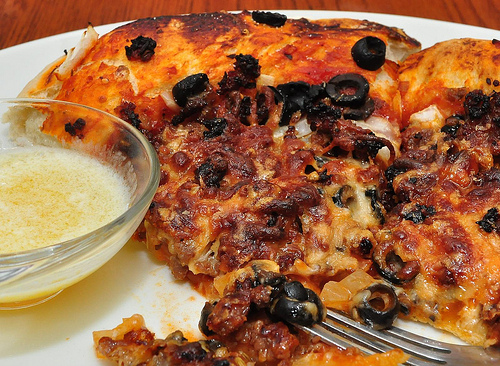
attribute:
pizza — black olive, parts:
[44, 13, 441, 362]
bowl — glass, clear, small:
[0, 111, 167, 265]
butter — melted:
[4, 144, 90, 221]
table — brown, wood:
[6, 16, 498, 328]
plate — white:
[22, 23, 479, 360]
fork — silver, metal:
[309, 285, 460, 351]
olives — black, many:
[271, 280, 324, 332]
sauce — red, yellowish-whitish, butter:
[9, 122, 117, 235]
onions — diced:
[406, 107, 440, 130]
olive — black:
[357, 41, 397, 71]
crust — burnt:
[101, 8, 390, 83]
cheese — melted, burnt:
[190, 161, 321, 255]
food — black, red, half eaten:
[25, 14, 448, 332]